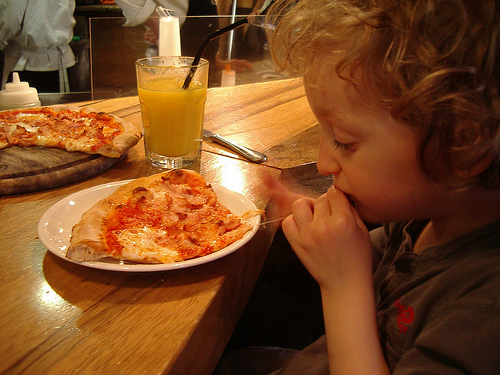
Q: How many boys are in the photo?
A: One.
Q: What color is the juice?
A: Yellow.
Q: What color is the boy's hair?
A: Red.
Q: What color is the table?
A: Brown.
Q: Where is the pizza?
A: On the plate.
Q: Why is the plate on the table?
A: To hold pizza.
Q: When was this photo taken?
A: While he ate pizza.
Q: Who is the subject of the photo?
A: The boy.